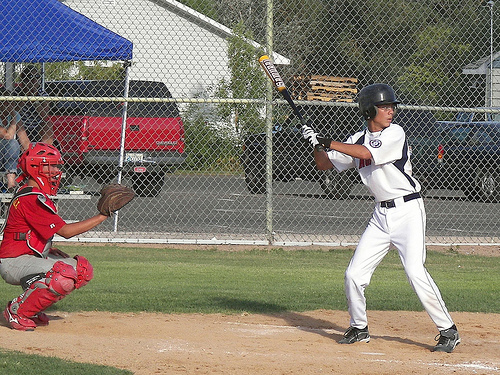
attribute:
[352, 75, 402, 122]
helmet — red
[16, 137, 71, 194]
helmet — red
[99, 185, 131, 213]
baseball glove — brown, leather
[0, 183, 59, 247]
chest gear — protective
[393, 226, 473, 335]
leg — red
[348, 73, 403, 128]
helmet — black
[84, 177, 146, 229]
catcher — brown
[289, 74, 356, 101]
pallets — brown, wooden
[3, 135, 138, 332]
catcher — red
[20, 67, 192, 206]
suv — red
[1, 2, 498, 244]
fence — chain-link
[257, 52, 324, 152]
bat — black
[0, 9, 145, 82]
tent — blue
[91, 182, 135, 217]
baseball glove — brown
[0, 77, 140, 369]
catcher — ready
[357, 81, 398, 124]
helmet — black